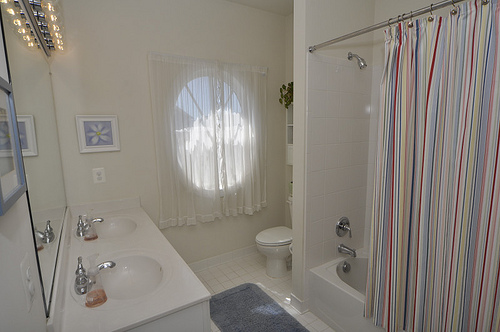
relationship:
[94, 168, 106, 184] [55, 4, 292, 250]
electrical socket on wall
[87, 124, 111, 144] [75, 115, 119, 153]
daisy flower in frame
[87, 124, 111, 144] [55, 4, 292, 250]
daisy flower on wall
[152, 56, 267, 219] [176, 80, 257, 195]
curtain covering window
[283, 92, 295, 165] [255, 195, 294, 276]
cabinet over toilet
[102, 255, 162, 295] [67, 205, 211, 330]
sink on vanity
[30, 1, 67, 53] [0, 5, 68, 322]
lights above mirror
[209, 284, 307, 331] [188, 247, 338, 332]
bath rug on floor